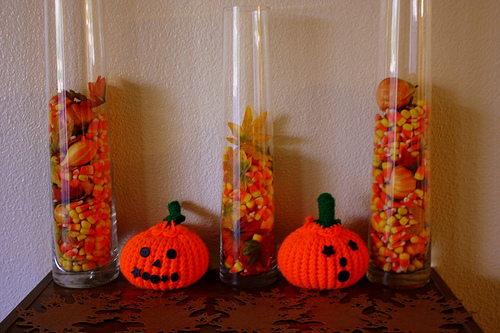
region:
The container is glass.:
[36, 0, 121, 298]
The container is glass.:
[206, 0, 276, 290]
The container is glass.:
[362, 0, 442, 297]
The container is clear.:
[40, 0, 125, 295]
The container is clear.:
[215, 0, 285, 296]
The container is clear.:
[366, 0, 449, 292]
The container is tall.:
[38, 0, 130, 292]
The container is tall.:
[211, 0, 285, 291]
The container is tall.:
[359, 0, 444, 305]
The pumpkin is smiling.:
[113, 178, 210, 317]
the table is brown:
[15, 263, 467, 328]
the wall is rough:
[16, 50, 69, 228]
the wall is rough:
[154, 62, 225, 181]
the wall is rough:
[284, 48, 383, 211]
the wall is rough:
[426, 50, 497, 245]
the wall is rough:
[98, 60, 226, 235]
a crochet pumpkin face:
[105, 193, 229, 293]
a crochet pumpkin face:
[271, 193, 410, 310]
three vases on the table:
[25, 21, 453, 326]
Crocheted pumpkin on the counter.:
[280, 185, 365, 293]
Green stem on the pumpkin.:
[310, 189, 341, 234]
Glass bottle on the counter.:
[366, 5, 438, 290]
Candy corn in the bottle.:
[225, 162, 274, 227]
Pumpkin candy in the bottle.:
[379, 164, 416, 201]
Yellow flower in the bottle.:
[223, 105, 273, 156]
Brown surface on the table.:
[2, 248, 480, 330]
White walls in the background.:
[0, 0, 495, 332]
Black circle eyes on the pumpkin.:
[132, 243, 183, 264]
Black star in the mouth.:
[127, 263, 146, 282]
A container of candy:
[221, 3, 276, 284]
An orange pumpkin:
[277, 194, 368, 288]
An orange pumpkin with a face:
[117, 200, 209, 290]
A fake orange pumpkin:
[119, 200, 207, 285]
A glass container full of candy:
[45, 0, 120, 286]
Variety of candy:
[223, 108, 273, 271]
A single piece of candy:
[378, 74, 413, 107]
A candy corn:
[414, 163, 426, 180]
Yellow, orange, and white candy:
[380, 161, 391, 181]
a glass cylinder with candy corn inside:
[220, 4, 277, 284]